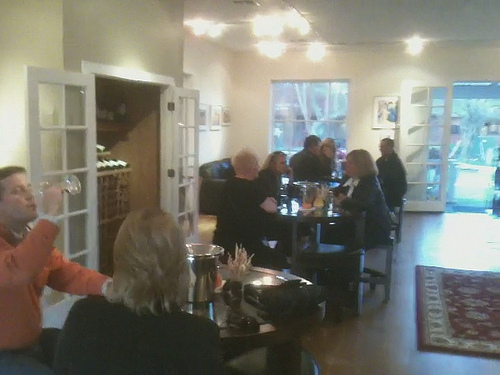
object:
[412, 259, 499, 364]
rug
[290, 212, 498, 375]
floor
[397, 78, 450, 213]
door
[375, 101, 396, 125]
picture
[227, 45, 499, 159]
wall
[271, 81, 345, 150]
window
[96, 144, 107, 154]
wine bottles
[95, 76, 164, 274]
pantry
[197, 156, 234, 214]
couch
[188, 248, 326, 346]
table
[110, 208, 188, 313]
head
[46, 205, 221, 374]
woman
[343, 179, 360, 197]
shirt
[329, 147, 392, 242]
woman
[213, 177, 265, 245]
shirt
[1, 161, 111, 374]
man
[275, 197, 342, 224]
table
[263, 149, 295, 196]
woman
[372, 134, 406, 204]
man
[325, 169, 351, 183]
table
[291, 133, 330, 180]
man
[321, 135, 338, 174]
woman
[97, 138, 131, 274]
wine rack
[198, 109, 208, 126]
pictures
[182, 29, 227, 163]
wall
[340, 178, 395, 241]
jacket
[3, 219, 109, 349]
sweater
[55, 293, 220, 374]
shirt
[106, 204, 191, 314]
hair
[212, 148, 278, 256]
women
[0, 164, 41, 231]
head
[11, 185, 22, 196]
eye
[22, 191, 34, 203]
nose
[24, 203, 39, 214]
mouth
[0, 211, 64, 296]
arm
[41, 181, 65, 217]
hand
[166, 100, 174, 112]
hinge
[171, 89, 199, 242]
door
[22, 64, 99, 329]
french door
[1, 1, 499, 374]
restaurant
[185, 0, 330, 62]
light fixtures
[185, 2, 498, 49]
ceiling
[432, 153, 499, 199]
patio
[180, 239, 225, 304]
ice bucket